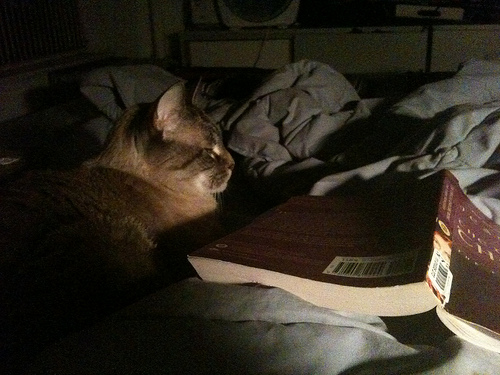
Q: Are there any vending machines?
A: No, there are no vending machines.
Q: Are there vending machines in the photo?
A: No, there are no vending machines.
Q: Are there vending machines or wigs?
A: No, there are no vending machines or wigs.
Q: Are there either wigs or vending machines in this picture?
A: No, there are no vending machines or wigs.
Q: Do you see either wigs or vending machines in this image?
A: No, there are no vending machines or wigs.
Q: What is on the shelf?
A: The fan is on the shelf.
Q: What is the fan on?
A: The fan is on the shelf.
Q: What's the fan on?
A: The fan is on the shelf.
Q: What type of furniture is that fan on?
A: The fan is on the shelf.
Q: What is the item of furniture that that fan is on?
A: The piece of furniture is a shelf.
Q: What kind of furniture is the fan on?
A: The fan is on the shelf.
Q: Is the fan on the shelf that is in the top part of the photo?
A: Yes, the fan is on the shelf.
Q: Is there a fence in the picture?
A: No, there are no fences.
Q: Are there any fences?
A: No, there are no fences.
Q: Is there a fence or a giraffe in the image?
A: No, there are no fences or giraffes.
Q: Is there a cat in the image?
A: Yes, there is a cat.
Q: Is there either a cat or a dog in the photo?
A: Yes, there is a cat.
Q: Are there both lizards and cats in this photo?
A: No, there is a cat but no lizards.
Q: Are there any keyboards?
A: No, there are no keyboards.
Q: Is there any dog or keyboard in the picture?
A: No, there are no keyboards or dogs.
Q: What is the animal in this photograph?
A: The animal is a cat.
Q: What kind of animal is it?
A: The animal is a cat.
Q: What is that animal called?
A: This is a cat.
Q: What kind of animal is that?
A: This is a cat.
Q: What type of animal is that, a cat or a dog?
A: This is a cat.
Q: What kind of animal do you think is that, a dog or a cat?
A: This is a cat.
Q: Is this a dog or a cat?
A: This is a cat.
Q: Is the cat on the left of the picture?
A: Yes, the cat is on the left of the image.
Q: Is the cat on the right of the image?
A: No, the cat is on the left of the image.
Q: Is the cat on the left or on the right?
A: The cat is on the left of the image.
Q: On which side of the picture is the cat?
A: The cat is on the left of the image.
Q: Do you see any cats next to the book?
A: Yes, there is a cat next to the book.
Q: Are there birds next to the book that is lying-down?
A: No, there is a cat next to the book.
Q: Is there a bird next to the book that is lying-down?
A: No, there is a cat next to the book.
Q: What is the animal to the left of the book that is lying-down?
A: The animal is a cat.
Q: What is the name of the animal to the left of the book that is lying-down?
A: The animal is a cat.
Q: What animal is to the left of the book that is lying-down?
A: The animal is a cat.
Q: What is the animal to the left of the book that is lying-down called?
A: The animal is a cat.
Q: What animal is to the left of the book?
A: The animal is a cat.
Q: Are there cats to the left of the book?
A: Yes, there is a cat to the left of the book.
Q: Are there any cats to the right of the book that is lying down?
A: No, the cat is to the left of the book.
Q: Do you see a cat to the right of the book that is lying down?
A: No, the cat is to the left of the book.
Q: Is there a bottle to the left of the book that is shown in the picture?
A: No, there is a cat to the left of the book.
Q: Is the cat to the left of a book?
A: Yes, the cat is to the left of a book.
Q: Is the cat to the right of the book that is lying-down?
A: No, the cat is to the left of the book.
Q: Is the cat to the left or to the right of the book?
A: The cat is to the left of the book.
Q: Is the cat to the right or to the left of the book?
A: The cat is to the left of the book.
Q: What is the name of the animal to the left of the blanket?
A: The animal is a cat.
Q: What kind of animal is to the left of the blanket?
A: The animal is a cat.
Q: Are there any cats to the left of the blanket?
A: Yes, there is a cat to the left of the blanket.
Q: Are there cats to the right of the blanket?
A: No, the cat is to the left of the blanket.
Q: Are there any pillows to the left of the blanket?
A: No, there is a cat to the left of the blanket.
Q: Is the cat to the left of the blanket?
A: Yes, the cat is to the left of the blanket.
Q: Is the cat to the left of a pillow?
A: No, the cat is to the left of the blanket.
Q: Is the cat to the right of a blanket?
A: No, the cat is to the left of a blanket.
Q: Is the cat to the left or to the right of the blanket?
A: The cat is to the left of the blanket.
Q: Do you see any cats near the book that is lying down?
A: Yes, there is a cat near the book.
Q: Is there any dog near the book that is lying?
A: No, there is a cat near the book.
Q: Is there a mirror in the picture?
A: No, there are no mirrors.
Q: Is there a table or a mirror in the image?
A: No, there are no mirrors or tables.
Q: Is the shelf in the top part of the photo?
A: Yes, the shelf is in the top of the image.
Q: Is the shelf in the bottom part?
A: No, the shelf is in the top of the image.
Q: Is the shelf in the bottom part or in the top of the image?
A: The shelf is in the top of the image.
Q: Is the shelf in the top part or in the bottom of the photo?
A: The shelf is in the top of the image.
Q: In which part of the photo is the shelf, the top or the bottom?
A: The shelf is in the top of the image.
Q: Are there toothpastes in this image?
A: No, there are no toothpastes.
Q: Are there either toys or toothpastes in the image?
A: No, there are no toothpastes or toys.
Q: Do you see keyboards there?
A: No, there are no keyboards.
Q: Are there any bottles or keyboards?
A: No, there are no keyboards or bottles.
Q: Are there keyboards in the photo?
A: No, there are no keyboards.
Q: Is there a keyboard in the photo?
A: No, there are no keyboards.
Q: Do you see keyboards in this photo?
A: No, there are no keyboards.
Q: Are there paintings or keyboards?
A: No, there are no keyboards or paintings.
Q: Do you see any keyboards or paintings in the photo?
A: No, there are no keyboards or paintings.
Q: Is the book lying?
A: Yes, the book is lying.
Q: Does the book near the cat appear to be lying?
A: Yes, the book is lying.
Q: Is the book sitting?
A: No, the book is lying.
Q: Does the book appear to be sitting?
A: No, the book is lying.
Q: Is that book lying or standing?
A: The book is lying.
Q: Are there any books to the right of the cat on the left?
A: Yes, there is a book to the right of the cat.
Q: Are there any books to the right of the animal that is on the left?
A: Yes, there is a book to the right of the cat.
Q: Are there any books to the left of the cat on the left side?
A: No, the book is to the right of the cat.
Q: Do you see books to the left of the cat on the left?
A: No, the book is to the right of the cat.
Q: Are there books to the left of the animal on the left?
A: No, the book is to the right of the cat.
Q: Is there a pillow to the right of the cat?
A: No, there is a book to the right of the cat.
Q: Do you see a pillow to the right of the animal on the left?
A: No, there is a book to the right of the cat.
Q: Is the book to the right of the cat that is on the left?
A: Yes, the book is to the right of the cat.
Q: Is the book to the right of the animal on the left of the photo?
A: Yes, the book is to the right of the cat.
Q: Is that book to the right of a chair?
A: No, the book is to the right of the cat.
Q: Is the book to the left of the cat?
A: No, the book is to the right of the cat.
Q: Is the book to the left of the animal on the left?
A: No, the book is to the right of the cat.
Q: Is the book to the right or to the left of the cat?
A: The book is to the right of the cat.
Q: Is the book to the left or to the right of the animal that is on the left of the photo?
A: The book is to the right of the cat.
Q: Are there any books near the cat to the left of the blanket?
A: Yes, there is a book near the cat.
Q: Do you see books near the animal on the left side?
A: Yes, there is a book near the cat.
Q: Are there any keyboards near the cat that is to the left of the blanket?
A: No, there is a book near the cat.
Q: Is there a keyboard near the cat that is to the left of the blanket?
A: No, there is a book near the cat.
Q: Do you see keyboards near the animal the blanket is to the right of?
A: No, there is a book near the cat.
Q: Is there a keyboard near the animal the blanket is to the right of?
A: No, there is a book near the cat.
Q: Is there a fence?
A: No, there are no fences.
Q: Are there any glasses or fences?
A: No, there are no fences or glasses.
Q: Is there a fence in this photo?
A: No, there are no fences.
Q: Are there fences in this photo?
A: No, there are no fences.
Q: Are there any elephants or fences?
A: No, there are no fences or elephants.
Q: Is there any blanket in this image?
A: Yes, there is a blanket.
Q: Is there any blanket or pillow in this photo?
A: Yes, there is a blanket.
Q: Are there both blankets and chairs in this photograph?
A: No, there is a blanket but no chairs.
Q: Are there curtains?
A: No, there are no curtains.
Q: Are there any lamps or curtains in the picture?
A: No, there are no curtains or lamps.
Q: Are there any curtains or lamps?
A: No, there are no curtains or lamps.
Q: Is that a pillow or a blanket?
A: That is a blanket.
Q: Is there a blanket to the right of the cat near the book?
A: Yes, there is a blanket to the right of the cat.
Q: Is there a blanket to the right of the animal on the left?
A: Yes, there is a blanket to the right of the cat.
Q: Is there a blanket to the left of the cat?
A: No, the blanket is to the right of the cat.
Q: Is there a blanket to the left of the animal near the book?
A: No, the blanket is to the right of the cat.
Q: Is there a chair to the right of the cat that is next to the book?
A: No, there is a blanket to the right of the cat.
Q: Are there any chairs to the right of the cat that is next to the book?
A: No, there is a blanket to the right of the cat.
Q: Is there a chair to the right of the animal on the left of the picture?
A: No, there is a blanket to the right of the cat.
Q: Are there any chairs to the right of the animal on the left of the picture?
A: No, there is a blanket to the right of the cat.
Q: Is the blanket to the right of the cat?
A: Yes, the blanket is to the right of the cat.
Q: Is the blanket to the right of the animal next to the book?
A: Yes, the blanket is to the right of the cat.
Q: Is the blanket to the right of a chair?
A: No, the blanket is to the right of the cat.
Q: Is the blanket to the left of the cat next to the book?
A: No, the blanket is to the right of the cat.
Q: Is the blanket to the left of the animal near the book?
A: No, the blanket is to the right of the cat.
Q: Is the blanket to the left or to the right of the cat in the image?
A: The blanket is to the right of the cat.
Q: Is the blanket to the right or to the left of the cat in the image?
A: The blanket is to the right of the cat.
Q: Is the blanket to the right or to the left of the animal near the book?
A: The blanket is to the right of the cat.